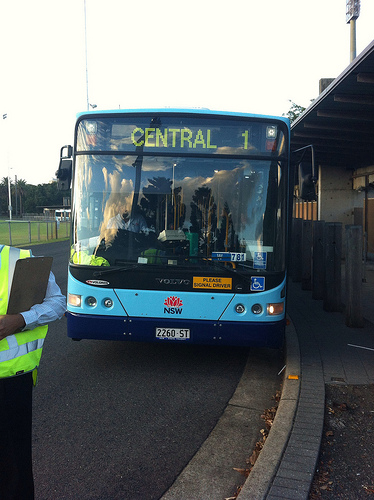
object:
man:
[0, 244, 66, 500]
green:
[0, 245, 49, 388]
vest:
[73, 251, 110, 267]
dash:
[93, 260, 251, 284]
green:
[71, 243, 110, 266]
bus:
[60, 108, 313, 347]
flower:
[164, 296, 183, 308]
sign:
[250, 276, 265, 291]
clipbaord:
[6, 256, 54, 316]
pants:
[0, 370, 35, 500]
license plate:
[156, 328, 191, 340]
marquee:
[131, 127, 248, 149]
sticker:
[193, 277, 232, 289]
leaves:
[229, 384, 283, 500]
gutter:
[160, 352, 286, 500]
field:
[0, 220, 70, 247]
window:
[70, 154, 278, 273]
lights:
[69, 293, 284, 315]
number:
[242, 131, 248, 150]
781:
[232, 254, 244, 261]